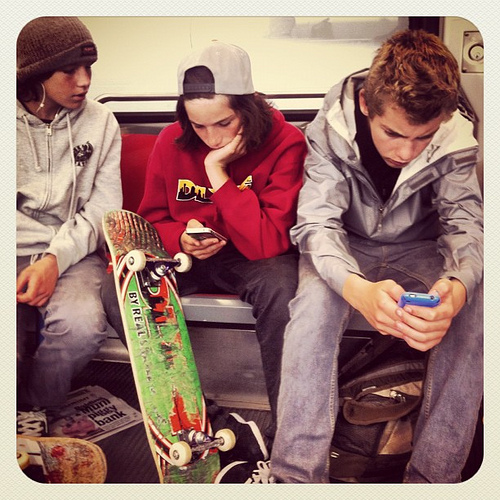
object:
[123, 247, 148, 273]
wheel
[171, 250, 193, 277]
wheel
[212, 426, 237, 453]
wheel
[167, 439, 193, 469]
wheel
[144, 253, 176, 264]
truck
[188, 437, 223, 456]
truck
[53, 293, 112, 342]
knee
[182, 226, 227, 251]
smartphone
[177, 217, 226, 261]
hand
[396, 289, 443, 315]
phone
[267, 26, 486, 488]
boy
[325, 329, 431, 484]
backpack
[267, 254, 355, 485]
legs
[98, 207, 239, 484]
skateboard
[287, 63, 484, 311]
jacket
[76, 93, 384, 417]
bus bench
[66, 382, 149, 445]
newspaper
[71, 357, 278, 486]
floor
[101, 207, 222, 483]
underside